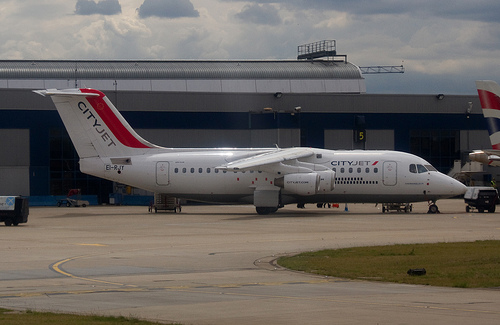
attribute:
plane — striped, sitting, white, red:
[33, 86, 475, 215]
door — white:
[377, 159, 402, 192]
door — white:
[153, 160, 173, 189]